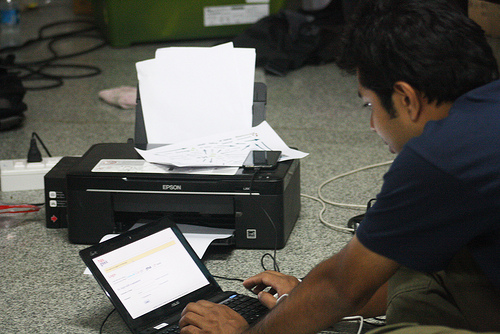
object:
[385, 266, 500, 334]
pants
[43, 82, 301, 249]
printer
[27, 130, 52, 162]
power cord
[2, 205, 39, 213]
strip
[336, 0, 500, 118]
dark hair.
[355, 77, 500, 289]
shirt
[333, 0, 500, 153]
head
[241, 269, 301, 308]
hand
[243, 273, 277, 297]
mouse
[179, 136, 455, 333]
arm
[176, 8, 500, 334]
man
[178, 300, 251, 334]
hand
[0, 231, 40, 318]
carpet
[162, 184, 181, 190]
logo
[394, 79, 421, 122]
ear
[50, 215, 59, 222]
light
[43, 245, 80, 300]
floor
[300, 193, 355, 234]
cable